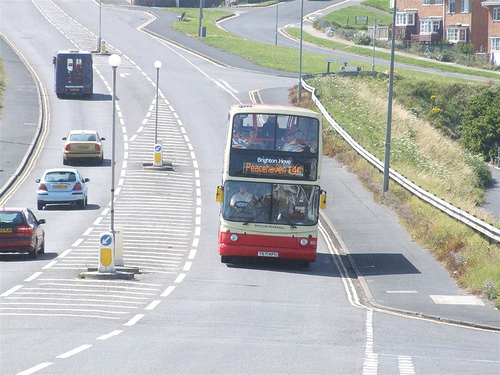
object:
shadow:
[313, 247, 430, 280]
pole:
[97, 50, 132, 265]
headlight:
[298, 235, 311, 249]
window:
[226, 181, 325, 231]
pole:
[381, 5, 401, 196]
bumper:
[216, 227, 323, 265]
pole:
[105, 55, 125, 269]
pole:
[148, 58, 169, 174]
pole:
[93, 0, 107, 52]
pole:
[379, 1, 403, 195]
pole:
[294, 3, 311, 97]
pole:
[272, 3, 281, 52]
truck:
[50, 47, 101, 98]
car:
[33, 165, 90, 208]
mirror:
[317, 188, 330, 212]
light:
[228, 233, 239, 243]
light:
[106, 54, 123, 69]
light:
[153, 58, 164, 70]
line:
[352, 306, 387, 375]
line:
[126, 78, 163, 148]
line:
[168, 39, 256, 118]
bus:
[218, 102, 330, 268]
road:
[148, 244, 459, 375]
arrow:
[99, 233, 114, 246]